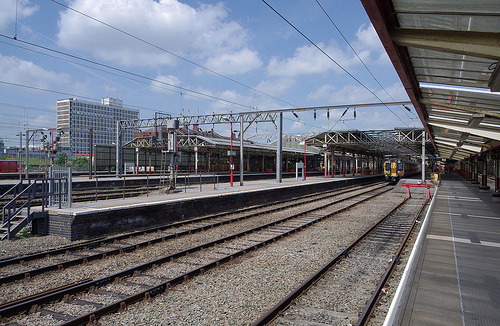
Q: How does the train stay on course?
A: Railroad tracks.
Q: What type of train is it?
A: Passenger train.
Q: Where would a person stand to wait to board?
A: The platform.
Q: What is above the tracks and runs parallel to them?
A: Wires.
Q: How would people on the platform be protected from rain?
A: Overhead cover.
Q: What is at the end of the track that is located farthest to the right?
A: A red barrier.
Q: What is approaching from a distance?
A: A yellow train.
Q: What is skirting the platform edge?
A: A white stripe.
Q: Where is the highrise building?
A: To the far left, beyond the two sets of railway tracks.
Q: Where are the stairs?
A: On the far right, at the end of the platform, closest to the right side of the oncoming train.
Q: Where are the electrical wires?
A: Hanging, vertically, over the train tracks.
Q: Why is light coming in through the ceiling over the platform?
A: There are spaces between the girders.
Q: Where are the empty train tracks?
A: On either side of the track with the oncoming train.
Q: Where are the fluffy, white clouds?
A: In the sky.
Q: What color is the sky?
A: Blue.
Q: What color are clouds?
A: White.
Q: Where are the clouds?
A: The sky.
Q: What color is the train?
A: Yellow.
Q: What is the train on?
A: The tracks.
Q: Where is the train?
A: The depot.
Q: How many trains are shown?
A: One.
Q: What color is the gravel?
A: Gray.